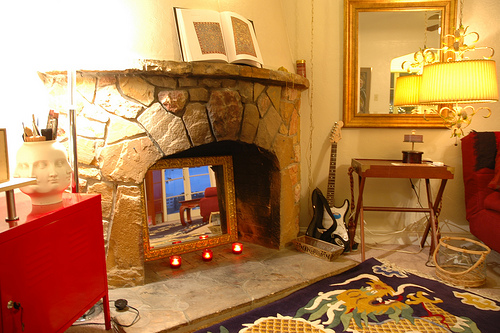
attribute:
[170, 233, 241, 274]
candles — red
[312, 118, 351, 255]
guitar — black, leaning, white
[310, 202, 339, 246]
strap — black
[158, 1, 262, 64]
book — open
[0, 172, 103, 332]
table — red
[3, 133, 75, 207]
vase — white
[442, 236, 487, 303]
basket — wooden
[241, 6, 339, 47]
wall — yellow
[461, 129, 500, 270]
couch — red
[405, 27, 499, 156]
light — hanging, on, yellow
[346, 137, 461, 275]
table — brown, wooden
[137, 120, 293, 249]
fireplace — in room, stone